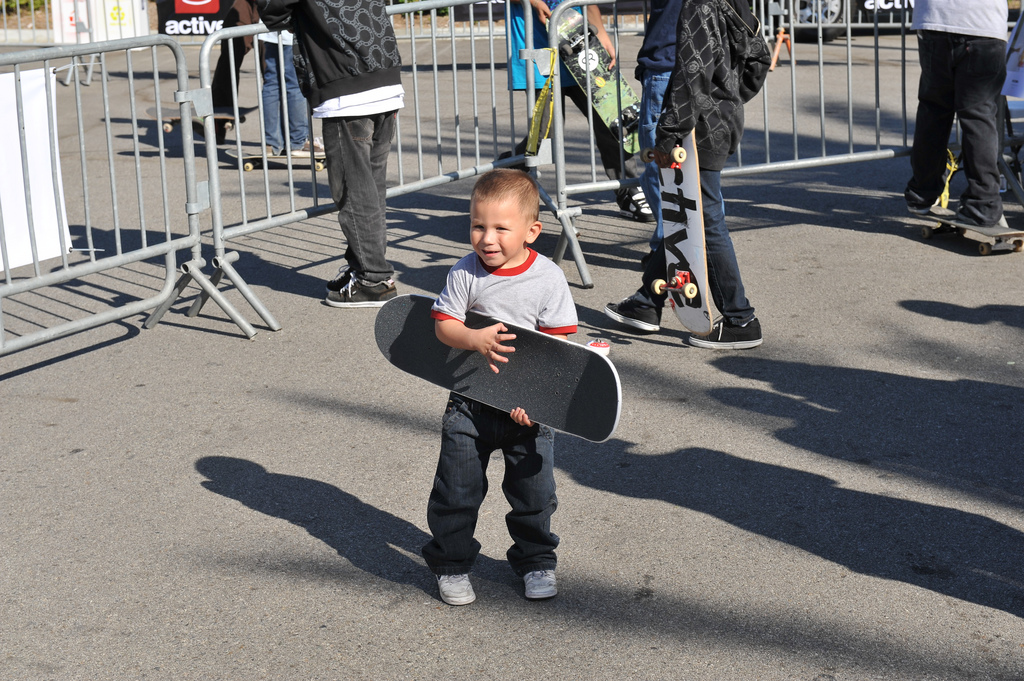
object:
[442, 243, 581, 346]
shirt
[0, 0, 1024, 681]
scene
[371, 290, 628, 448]
board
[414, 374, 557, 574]
jeans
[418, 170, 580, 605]
boy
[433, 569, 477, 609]
shoe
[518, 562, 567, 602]
shoe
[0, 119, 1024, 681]
street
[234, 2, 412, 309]
man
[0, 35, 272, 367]
fence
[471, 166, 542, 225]
hair